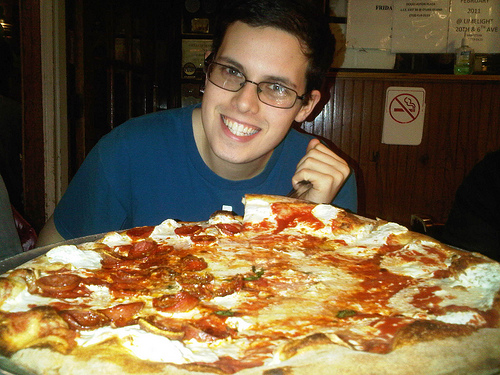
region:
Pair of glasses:
[199, 55, 306, 108]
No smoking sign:
[379, 82, 424, 144]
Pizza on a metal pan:
[0, 195, 497, 372]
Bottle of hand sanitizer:
[453, 35, 473, 72]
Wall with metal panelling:
[303, 67, 497, 229]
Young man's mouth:
[219, 113, 261, 142]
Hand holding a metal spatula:
[290, 136, 350, 203]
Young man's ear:
[296, 89, 322, 124]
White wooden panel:
[34, 1, 69, 224]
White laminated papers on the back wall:
[348, 1, 497, 52]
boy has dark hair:
[222, 16, 356, 106]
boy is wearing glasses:
[187, 62, 304, 114]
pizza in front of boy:
[7, 200, 498, 363]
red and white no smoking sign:
[370, 77, 430, 137]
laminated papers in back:
[359, 0, 462, 63]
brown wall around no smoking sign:
[330, 84, 488, 229]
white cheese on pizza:
[45, 237, 403, 371]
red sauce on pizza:
[131, 242, 434, 355]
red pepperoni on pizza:
[111, 236, 241, 337]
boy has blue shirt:
[75, 112, 362, 254]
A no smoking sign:
[379, 82, 426, 152]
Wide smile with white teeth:
[216, 109, 269, 146]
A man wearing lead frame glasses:
[204, 51, 304, 115]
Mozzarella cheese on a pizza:
[45, 238, 102, 276]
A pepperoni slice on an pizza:
[32, 264, 84, 297]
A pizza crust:
[392, 320, 484, 365]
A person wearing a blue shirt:
[110, 112, 220, 202]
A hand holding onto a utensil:
[280, 135, 350, 205]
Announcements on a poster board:
[347, 3, 497, 81]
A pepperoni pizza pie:
[0, 192, 492, 372]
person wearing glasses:
[204, 59, 304, 113]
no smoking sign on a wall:
[375, 85, 428, 150]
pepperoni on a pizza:
[40, 238, 218, 342]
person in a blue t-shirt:
[48, 8, 362, 247]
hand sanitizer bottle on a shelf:
[449, 25, 473, 79]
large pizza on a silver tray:
[8, 189, 494, 372]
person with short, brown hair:
[200, 3, 337, 155]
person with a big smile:
[211, 108, 267, 146]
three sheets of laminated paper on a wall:
[343, 1, 498, 60]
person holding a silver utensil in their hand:
[278, 140, 353, 209]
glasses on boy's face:
[195, 60, 319, 105]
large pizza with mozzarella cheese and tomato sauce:
[11, 190, 497, 366]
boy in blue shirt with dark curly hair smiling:
[30, 8, 360, 255]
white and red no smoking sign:
[383, 77, 430, 150]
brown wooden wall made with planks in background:
[296, 58, 498, 220]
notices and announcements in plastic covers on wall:
[346, 0, 497, 71]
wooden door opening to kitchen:
[68, 0, 206, 182]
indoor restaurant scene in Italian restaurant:
[5, 1, 498, 367]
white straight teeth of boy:
[218, 117, 267, 143]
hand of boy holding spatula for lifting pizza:
[287, 136, 356, 201]